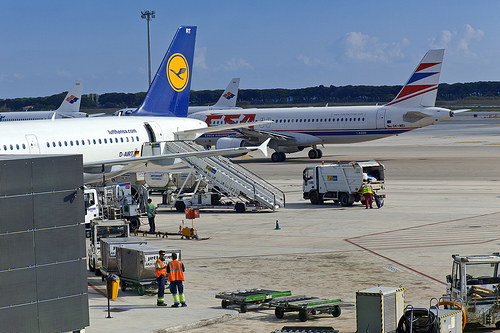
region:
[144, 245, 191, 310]
two people standing on the tarmac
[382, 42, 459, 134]
red white and blue tail wing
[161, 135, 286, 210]
steps that go up to the airplane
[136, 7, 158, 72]
light pole behind the planes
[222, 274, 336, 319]
empty green trailers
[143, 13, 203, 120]
blue and yellow tail wing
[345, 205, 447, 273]
red line on the pavement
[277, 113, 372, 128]
row of airplane windows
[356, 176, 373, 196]
person wearing a yellow vest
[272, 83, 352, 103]
treeline in the distance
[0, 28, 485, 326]
Multiple planes on a tarmac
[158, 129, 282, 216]
The plane's exit stairwell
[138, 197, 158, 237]
A man in a yellow vest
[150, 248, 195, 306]
Two men in orange vests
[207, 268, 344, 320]
Two green pallets with wheels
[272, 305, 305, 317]
Black wheels on the pallets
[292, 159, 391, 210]
A small white loading truck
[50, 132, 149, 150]
Small windows along the aircraft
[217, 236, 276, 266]
Cement beneath the planes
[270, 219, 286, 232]
A blue traffic cone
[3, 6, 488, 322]
activity on an airport runway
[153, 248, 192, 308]
two men in orange vests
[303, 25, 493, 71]
fluffy white clouds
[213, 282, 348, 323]
two green platforms with wheels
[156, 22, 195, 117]
blue and yellow airplane tail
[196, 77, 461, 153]
large commercial airplane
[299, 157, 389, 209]
truck for carrying luggage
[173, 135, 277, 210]
white staircase to a plane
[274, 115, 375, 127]
row of windows on an airplane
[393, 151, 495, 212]
brown cement on the airport runway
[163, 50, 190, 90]
the logo on the tail of the plane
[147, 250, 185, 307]
men standing around on the tarmac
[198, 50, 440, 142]
a plane sitting on the runway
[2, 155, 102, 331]
a big grey container sitting off to the side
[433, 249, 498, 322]
a little car sitting on the tarmac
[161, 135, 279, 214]
a flight of steps to help people get off the plane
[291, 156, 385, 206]
another car sitting on the tarmac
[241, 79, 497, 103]
a line of trees next to the runway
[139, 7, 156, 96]
a street light next to the trees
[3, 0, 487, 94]
the blue sky above everything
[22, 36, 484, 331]
planes on the ground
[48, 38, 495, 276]
two airplanes on the ground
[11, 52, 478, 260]
airplanes on the ground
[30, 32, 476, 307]
two white planes on the ground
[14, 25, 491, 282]
two white airplanes on the ground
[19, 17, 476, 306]
two large planes on the ground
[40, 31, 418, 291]
two large airplanes on ground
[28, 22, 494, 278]
two large white airplanes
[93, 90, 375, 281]
airplane with stairs connected